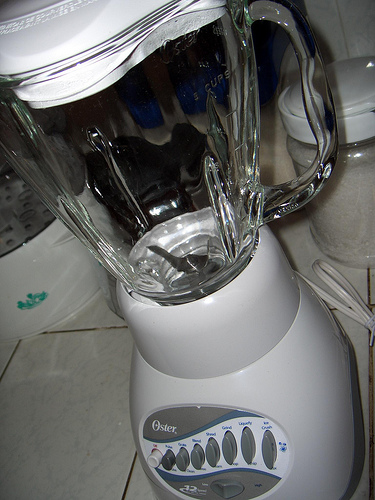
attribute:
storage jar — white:
[327, 180, 373, 236]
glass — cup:
[4, 3, 346, 307]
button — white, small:
[147, 448, 164, 467]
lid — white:
[3, 3, 181, 110]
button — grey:
[205, 437, 221, 467]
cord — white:
[306, 251, 374, 327]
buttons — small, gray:
[144, 423, 279, 472]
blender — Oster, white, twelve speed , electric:
[1, 2, 366, 498]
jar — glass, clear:
[0, 0, 339, 305]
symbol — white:
[151, 416, 182, 438]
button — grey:
[141, 402, 294, 498]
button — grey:
[239, 423, 258, 465]